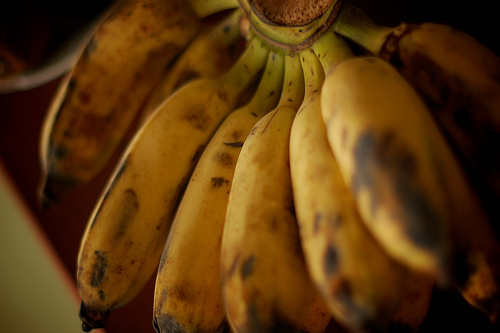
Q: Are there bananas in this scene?
A: Yes, there is a banana.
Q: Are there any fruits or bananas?
A: Yes, there is a banana.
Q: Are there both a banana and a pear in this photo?
A: No, there is a banana but no pears.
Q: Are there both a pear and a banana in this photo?
A: No, there is a banana but no pears.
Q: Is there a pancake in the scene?
A: No, there are no pancakes.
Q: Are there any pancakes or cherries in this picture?
A: No, there are no pancakes or cherries.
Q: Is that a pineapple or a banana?
A: That is a banana.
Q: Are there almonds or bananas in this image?
A: Yes, there is a banana.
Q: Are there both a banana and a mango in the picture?
A: No, there is a banana but no mangoes.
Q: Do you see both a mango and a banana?
A: No, there is a banana but no mangoes.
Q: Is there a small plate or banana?
A: Yes, there is a small banana.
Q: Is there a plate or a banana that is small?
A: Yes, the banana is small.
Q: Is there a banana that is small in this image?
A: Yes, there is a small banana.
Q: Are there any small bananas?
A: Yes, there is a small banana.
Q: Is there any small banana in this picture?
A: Yes, there is a small banana.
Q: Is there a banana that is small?
A: Yes, there is a banana that is small.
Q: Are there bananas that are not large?
A: Yes, there is a small banana.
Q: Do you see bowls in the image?
A: No, there are no bowls.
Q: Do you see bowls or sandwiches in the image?
A: No, there are no bowls or sandwiches.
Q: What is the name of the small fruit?
A: The fruit is a banana.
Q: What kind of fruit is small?
A: The fruit is a banana.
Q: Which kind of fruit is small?
A: The fruit is a banana.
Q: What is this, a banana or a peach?
A: This is a banana.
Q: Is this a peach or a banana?
A: This is a banana.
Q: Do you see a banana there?
A: Yes, there is a banana.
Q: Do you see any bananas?
A: Yes, there is a banana.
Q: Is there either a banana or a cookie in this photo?
A: Yes, there is a banana.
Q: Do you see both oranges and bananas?
A: No, there is a banana but no oranges.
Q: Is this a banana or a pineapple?
A: This is a banana.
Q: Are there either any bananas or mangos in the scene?
A: Yes, there is a banana.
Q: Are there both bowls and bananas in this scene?
A: No, there is a banana but no bowls.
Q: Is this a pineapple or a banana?
A: This is a banana.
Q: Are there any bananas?
A: Yes, there is a banana.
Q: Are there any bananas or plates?
A: Yes, there is a banana.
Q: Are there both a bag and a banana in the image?
A: No, there is a banana but no bags.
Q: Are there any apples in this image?
A: No, there are no apples.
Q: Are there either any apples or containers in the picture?
A: No, there are no apples or containers.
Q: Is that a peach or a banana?
A: That is a banana.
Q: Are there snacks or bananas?
A: Yes, there is a banana.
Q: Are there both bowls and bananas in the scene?
A: No, there is a banana but no bowls.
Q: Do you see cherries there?
A: No, there are no cherries.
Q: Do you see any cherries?
A: No, there are no cherries.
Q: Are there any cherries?
A: No, there are no cherries.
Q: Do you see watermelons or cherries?
A: No, there are no cherries or watermelons.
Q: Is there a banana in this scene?
A: Yes, there is a banana.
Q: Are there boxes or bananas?
A: Yes, there is a banana.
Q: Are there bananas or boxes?
A: Yes, there is a banana.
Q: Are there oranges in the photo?
A: No, there are no oranges.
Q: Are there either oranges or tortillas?
A: No, there are no oranges or tortillas.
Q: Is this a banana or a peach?
A: This is a banana.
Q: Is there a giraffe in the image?
A: No, there are no giraffes.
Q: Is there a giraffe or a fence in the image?
A: No, there are no giraffes or fences.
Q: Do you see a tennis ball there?
A: No, there are no tennis balls.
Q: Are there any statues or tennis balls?
A: No, there are no tennis balls or statues.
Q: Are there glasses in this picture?
A: No, there are no glasses.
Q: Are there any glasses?
A: No, there are no glasses.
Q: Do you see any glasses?
A: No, there are no glasses.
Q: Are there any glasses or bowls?
A: No, there are no glasses or bowls.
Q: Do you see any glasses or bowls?
A: No, there are no glasses or bowls.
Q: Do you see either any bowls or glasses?
A: No, there are no glasses or bowls.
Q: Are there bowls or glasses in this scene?
A: No, there are no glasses or bowls.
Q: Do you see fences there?
A: No, there are no fences.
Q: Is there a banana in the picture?
A: Yes, there are bananas.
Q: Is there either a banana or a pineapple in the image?
A: Yes, there are bananas.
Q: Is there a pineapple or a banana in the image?
A: Yes, there are bananas.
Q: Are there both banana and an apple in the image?
A: No, there are bananas but no apples.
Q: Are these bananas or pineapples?
A: These are bananas.